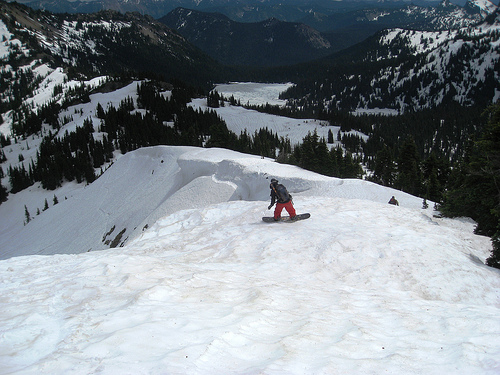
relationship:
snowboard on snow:
[256, 213, 313, 227] [9, 146, 499, 373]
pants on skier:
[272, 199, 299, 220] [262, 177, 299, 220]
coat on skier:
[262, 184, 294, 207] [262, 177, 299, 220]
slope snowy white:
[6, 147, 183, 254] [213, 77, 302, 111]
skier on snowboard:
[262, 177, 299, 220] [256, 213, 313, 223]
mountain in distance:
[158, 4, 375, 76] [194, 0, 469, 20]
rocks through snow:
[102, 218, 138, 250] [9, 146, 499, 373]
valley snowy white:
[195, 88, 369, 152] [213, 77, 302, 111]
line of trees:
[127, 78, 182, 124] [1, 14, 95, 122]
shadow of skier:
[265, 222, 308, 233] [262, 177, 299, 220]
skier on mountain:
[262, 177, 299, 220] [158, 4, 375, 76]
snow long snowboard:
[9, 146, 499, 373] [256, 213, 313, 223]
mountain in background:
[158, 4, 375, 76] [150, 8, 414, 65]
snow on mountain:
[9, 146, 499, 373] [158, 4, 375, 76]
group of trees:
[351, 31, 420, 58] [1, 14, 95, 122]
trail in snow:
[127, 278, 180, 309] [9, 146, 499, 373]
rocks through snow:
[92, 216, 146, 257] [9, 146, 499, 373]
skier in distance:
[262, 177, 299, 220] [194, 0, 469, 20]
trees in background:
[1, 14, 95, 122] [150, 8, 414, 65]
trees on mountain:
[1, 14, 95, 122] [158, 4, 375, 76]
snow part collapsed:
[9, 146, 499, 373] [208, 347, 261, 372]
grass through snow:
[161, 157, 167, 165] [9, 146, 499, 373]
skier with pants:
[262, 177, 299, 220] [272, 199, 299, 220]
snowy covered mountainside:
[53, 79, 153, 120] [11, 2, 247, 106]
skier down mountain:
[262, 177, 299, 220] [158, 4, 375, 76]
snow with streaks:
[9, 146, 499, 373] [424, 260, 482, 281]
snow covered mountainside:
[9, 146, 499, 373] [11, 2, 247, 106]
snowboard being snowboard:
[256, 213, 313, 227] [256, 213, 313, 223]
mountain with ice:
[158, 4, 375, 76] [214, 79, 267, 97]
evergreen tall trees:
[270, 127, 374, 188] [1, 14, 95, 122]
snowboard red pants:
[256, 213, 313, 223] [272, 199, 299, 220]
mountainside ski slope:
[11, 2, 247, 106] [6, 147, 183, 254]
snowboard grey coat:
[256, 213, 313, 223] [266, 182, 294, 207]